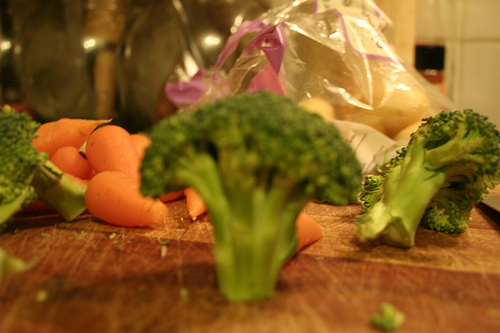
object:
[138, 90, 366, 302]
broccoli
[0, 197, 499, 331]
table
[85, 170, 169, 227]
carrot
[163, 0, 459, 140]
bag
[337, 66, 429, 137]
potatoe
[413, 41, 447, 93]
bottle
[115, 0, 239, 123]
bowl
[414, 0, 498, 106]
wall